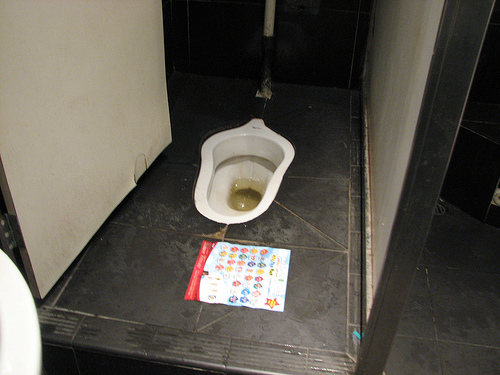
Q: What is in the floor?
A: A toilet.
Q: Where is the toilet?
A: In the floor.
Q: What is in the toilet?
A: Dirty liquid.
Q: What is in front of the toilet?
A: Paper.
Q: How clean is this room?
A: Dirty.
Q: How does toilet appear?
A: In the floor.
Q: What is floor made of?
A: Black tiles.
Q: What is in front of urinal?
A: Paper.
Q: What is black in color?
A: The floor.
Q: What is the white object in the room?
A: A toilet.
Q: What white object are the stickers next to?
A: The toilet.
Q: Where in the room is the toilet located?
A: In the ground.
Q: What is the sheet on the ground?
A: Stickers.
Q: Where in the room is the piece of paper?
A: On the ground.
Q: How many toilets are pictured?
A: One.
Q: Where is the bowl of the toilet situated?
A: Underground.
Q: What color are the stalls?
A: White.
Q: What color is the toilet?
A: White.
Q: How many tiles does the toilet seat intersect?
A: Four.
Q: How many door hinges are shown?
A: One.